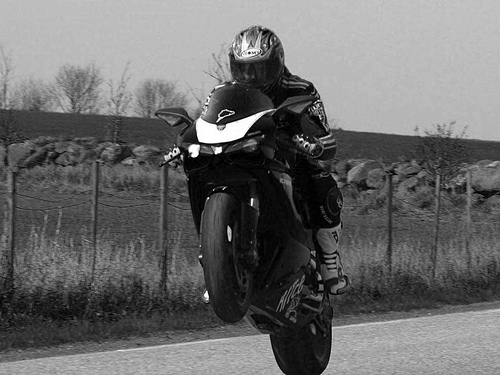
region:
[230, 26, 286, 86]
the man is wearing a motocycle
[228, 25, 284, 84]
the motorcycle has a printed graphic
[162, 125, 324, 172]
the man is holding on to the handle bars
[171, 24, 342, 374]
the man is doing a wheelie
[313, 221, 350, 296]
the man is wearing boots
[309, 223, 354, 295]
the boots are white in color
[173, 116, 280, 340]
the front of the motorcycle is up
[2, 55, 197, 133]
trees are in the background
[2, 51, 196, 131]
the trees are bare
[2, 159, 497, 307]
posts run along the road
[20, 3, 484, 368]
This is on a country road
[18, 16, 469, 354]
This photo is in black and white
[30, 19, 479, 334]
This photo is monochromatic style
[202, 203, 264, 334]
This tire is black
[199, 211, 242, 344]
This tire is made of rubber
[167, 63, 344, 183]
The bike is black and white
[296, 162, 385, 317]
This is a protective boot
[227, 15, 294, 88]
This man has a helmet on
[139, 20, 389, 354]
This man is riding a motorcycle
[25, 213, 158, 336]
This is tall grass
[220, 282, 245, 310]
part of a wheel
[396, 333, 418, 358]
[art of a road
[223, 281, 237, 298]
edge of a road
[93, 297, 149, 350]
edge fo a road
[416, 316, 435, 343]
[part of a road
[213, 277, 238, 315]
part of a wheel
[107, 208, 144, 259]
part of a fence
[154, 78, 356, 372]
motorcycle in air being driven by man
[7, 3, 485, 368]
black and white photograph of man on bike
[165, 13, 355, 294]
man on motorcycle with helmet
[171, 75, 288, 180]
front windshield of motorcycle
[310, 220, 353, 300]
white motorcycle boots on man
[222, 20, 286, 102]
decorated helmet on man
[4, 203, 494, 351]
tall grass lining road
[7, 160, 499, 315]
wooden post and wire fence along road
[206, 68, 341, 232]
black and striped motorcycle outfit on man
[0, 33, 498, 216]
rocks and trees in distance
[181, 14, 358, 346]
A person riding a motorcycle.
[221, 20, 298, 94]
Helmet on the head.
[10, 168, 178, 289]
Gate around the empty lot.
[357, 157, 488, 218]
A rock wall on side of road.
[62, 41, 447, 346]
The picture is black and white.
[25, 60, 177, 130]
Trees on the field.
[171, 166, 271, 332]
The wheel is not touching the ground.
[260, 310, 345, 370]
The back tire is on teh road.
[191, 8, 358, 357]
The person is doing a trick on the motorcycle.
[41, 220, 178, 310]
Weeds against the fence.